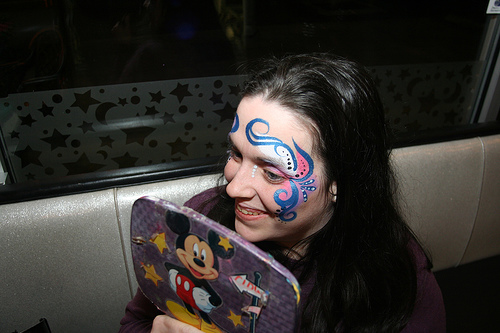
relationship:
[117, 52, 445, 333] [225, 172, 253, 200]
woman unpainted nose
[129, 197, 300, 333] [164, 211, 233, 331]
mirror painted with mickey mouse art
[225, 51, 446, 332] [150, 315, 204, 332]
woman has a hand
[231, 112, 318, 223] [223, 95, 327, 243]
paint on her face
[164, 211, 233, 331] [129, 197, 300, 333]
mickey mouse on mirror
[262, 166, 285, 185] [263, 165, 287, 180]
left eye has pink eye shadow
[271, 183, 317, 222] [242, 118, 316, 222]
cheek has face paint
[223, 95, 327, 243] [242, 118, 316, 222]
face has face paint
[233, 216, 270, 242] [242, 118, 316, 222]
chin has no face paint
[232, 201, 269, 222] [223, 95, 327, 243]
smile on her face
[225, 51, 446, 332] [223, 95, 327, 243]
woman's face painted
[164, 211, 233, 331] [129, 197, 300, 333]
mickey mouse painted on mirror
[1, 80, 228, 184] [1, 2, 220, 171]
banner outside night time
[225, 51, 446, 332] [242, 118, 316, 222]
woman has face paint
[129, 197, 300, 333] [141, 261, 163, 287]
mirror has yellow stars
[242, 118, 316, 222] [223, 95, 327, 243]
face paint on her face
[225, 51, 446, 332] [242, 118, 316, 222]
woman's face has face paint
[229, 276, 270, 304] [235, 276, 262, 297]
arrow has pink writing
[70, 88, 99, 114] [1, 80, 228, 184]
stars on banner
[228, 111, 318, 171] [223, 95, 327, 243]
face paint on her face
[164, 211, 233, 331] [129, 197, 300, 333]
mickey mouse on purple mirror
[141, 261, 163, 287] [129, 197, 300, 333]
gold star on mirror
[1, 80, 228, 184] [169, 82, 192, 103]
white banner with stars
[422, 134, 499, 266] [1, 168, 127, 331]
cushions of a bench